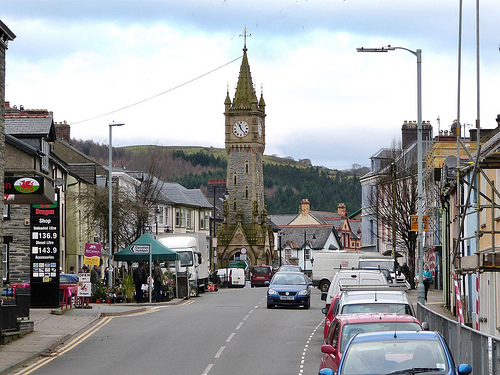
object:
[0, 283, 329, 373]
road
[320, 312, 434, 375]
car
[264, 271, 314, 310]
car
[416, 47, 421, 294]
pole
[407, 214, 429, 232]
sign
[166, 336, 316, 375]
ground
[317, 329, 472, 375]
car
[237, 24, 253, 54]
weather vane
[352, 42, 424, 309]
light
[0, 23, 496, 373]
city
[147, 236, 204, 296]
truck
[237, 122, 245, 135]
hands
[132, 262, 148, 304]
person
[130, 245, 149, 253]
sign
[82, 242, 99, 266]
sign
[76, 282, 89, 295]
sign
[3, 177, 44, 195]
sign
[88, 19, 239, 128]
cloudy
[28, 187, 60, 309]
sign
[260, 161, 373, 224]
trees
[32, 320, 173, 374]
ground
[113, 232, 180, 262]
tent top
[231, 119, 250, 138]
bright sun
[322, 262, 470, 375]
cars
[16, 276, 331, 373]
street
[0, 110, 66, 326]
station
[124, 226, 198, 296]
tent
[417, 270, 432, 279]
shirt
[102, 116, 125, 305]
street light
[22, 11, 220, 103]
sky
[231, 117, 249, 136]
clock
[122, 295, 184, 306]
curb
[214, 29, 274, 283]
building